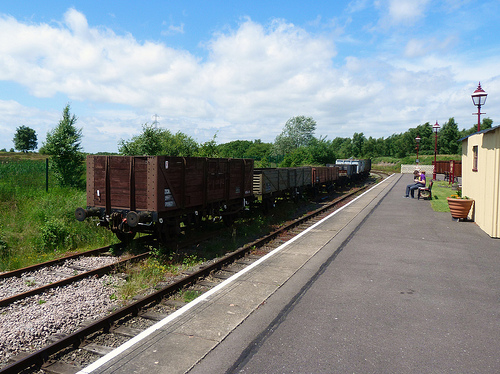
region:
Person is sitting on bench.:
[401, 168, 433, 201]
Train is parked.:
[67, 149, 380, 256]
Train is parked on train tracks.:
[0, 142, 376, 372]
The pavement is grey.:
[107, 155, 494, 372]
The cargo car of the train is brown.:
[84, 148, 259, 256]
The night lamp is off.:
[469, 75, 489, 134]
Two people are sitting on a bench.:
[402, 167, 432, 204]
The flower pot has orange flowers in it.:
[443, 189, 475, 224]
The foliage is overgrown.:
[2, 159, 115, 274]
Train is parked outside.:
[65, 152, 384, 257]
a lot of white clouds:
[5, 44, 437, 102]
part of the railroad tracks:
[0, 256, 102, 305]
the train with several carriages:
[87, 152, 372, 222]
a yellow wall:
[474, 139, 496, 234]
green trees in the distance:
[339, 131, 412, 161]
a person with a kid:
[404, 169, 426, 196]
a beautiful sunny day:
[8, 7, 486, 91]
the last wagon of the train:
[86, 158, 255, 219]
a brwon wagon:
[91, 153, 249, 213]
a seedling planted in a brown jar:
[446, 187, 471, 223]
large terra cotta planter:
[447, 195, 472, 217]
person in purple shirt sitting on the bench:
[405, 169, 425, 197]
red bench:
[416, 179, 435, 200]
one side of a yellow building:
[457, 125, 497, 234]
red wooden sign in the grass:
[447, 159, 454, 181]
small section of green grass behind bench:
[425, 177, 460, 209]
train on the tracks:
[75, 150, 372, 247]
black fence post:
[43, 158, 50, 191]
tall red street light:
[471, 80, 486, 130]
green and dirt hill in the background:
[370, 153, 460, 171]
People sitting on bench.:
[402, 158, 439, 208]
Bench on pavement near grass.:
[402, 164, 460, 234]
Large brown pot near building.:
[438, 181, 482, 231]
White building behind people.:
[458, 120, 498, 240]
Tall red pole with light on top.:
[421, 126, 451, 169]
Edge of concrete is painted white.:
[155, 171, 391, 276]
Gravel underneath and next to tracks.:
[51, 248, 108, 311]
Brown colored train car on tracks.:
[104, 140, 238, 232]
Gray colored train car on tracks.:
[265, 168, 307, 203]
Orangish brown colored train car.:
[310, 155, 342, 185]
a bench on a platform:
[265, 163, 439, 238]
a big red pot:
[446, 189, 476, 223]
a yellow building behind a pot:
[442, 123, 499, 246]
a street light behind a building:
[455, 78, 499, 242]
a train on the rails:
[29, 141, 372, 306]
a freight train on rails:
[48, 130, 383, 294]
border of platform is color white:
[81, 223, 341, 370]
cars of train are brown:
[58, 133, 351, 235]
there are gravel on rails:
[1, 243, 143, 351]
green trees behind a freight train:
[56, 103, 374, 270]